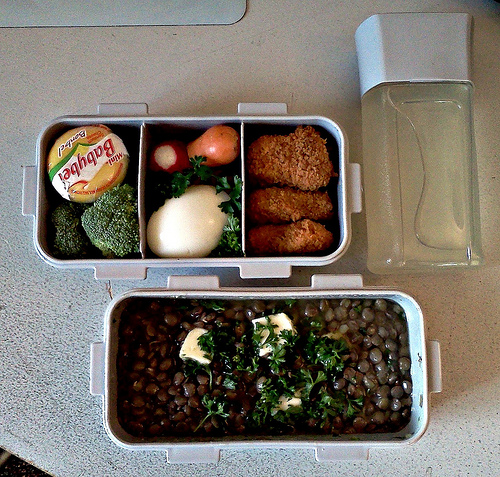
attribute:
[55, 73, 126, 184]
cheese — round, small, mini, mozzarella, packaged, surrounded, babybell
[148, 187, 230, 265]
eggs — boiled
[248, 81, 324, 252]
nuggets — chicken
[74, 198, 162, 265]
broccoli — raw, crowned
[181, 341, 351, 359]
butter — herbed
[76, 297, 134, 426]
dish — full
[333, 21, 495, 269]
canister — plastic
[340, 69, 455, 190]
bottle — capped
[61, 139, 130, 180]
print — red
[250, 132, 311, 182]
meat — breaded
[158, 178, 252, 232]
egg — boiled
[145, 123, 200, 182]
radish — here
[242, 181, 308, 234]
chicken — breaded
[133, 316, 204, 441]
beans — cooked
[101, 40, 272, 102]
table — granite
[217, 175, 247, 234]
parsley — used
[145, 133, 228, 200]
radishes — boxed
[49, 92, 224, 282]
bowl — rectangular